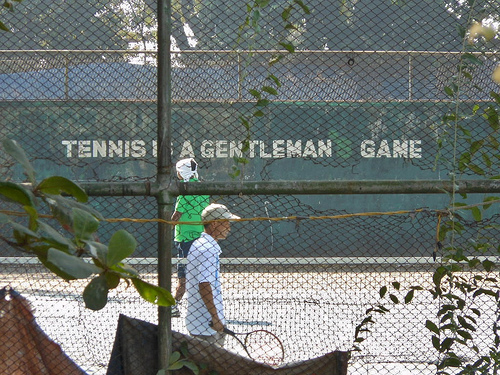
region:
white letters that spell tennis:
[61, 126, 147, 180]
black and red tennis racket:
[192, 312, 295, 371]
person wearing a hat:
[193, 195, 257, 249]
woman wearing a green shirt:
[164, 160, 229, 251]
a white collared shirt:
[184, 231, 244, 353]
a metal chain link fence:
[274, 226, 381, 341]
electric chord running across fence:
[36, 183, 445, 235]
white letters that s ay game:
[318, 118, 425, 183]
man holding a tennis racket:
[139, 195, 301, 369]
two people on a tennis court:
[125, 153, 287, 373]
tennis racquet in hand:
[195, 308, 292, 366]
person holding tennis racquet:
[165, 195, 303, 371]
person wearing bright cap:
[186, 196, 256, 260]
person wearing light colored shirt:
[179, 190, 243, 345]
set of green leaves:
[0, 143, 164, 315]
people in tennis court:
[42, 105, 413, 364]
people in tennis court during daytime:
[22, 126, 389, 367]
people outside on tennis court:
[85, 118, 396, 361]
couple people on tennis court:
[115, 123, 335, 363]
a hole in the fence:
[259, 122, 479, 263]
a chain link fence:
[144, 80, 426, 315]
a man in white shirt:
[158, 182, 270, 357]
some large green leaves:
[43, 207, 164, 317]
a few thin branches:
[385, 244, 482, 354]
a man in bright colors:
[163, 142, 223, 327]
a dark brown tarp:
[95, 301, 361, 371]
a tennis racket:
[207, 318, 305, 367]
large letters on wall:
[53, 130, 434, 177]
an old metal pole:
[142, 90, 191, 347]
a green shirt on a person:
[172, 171, 219, 244]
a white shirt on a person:
[181, 232, 234, 335]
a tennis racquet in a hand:
[204, 307, 288, 363]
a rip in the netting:
[268, 145, 492, 230]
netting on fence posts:
[1, 1, 493, 371]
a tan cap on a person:
[192, 200, 243, 222]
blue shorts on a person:
[170, 235, 210, 270]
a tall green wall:
[5, 97, 496, 252]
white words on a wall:
[49, 128, 423, 163]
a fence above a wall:
[2, 47, 495, 97]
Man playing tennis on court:
[184, 196, 300, 373]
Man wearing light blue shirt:
[180, 200, 243, 337]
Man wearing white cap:
[196, 202, 242, 243]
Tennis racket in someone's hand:
[205, 316, 297, 371]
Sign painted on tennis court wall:
[58, 128, 431, 164]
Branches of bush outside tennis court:
[0, 170, 178, 325]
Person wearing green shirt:
[170, 148, 208, 263]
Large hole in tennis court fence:
[252, 140, 498, 230]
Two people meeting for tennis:
[160, 148, 288, 373]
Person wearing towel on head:
[170, 153, 201, 189]